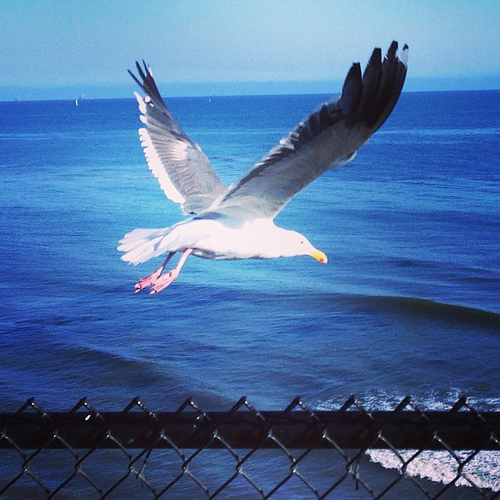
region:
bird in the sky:
[87, 35, 432, 333]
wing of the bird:
[241, 30, 438, 215]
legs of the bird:
[95, 250, 192, 335]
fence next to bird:
[190, 355, 330, 495]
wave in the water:
[391, 281, 441, 336]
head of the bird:
[270, 207, 340, 288]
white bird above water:
[85, 35, 435, 301]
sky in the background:
[222, 15, 294, 70]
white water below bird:
[423, 454, 455, 496]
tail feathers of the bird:
[118, 218, 188, 269]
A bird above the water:
[121, 64, 417, 289]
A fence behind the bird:
[1, 410, 499, 499]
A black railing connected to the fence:
[5, 410, 499, 445]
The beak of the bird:
[311, 244, 327, 267]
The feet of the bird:
[140, 260, 177, 292]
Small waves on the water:
[366, 288, 487, 319]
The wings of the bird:
[129, 58, 404, 219]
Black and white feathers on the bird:
[252, 110, 372, 193]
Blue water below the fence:
[111, 307, 420, 383]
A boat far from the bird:
[74, 99, 81, 106]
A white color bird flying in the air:
[51, 34, 452, 311]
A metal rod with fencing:
[10, 408, 487, 481]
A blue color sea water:
[25, 118, 98, 220]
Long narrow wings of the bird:
[121, 40, 416, 170]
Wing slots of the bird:
[331, 35, 454, 115]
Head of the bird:
[279, 221, 335, 278]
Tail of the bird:
[103, 217, 178, 259]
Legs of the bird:
[129, 247, 200, 309]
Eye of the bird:
[292, 233, 309, 248]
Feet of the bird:
[132, 274, 171, 305]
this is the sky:
[63, 3, 132, 61]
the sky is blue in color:
[124, 1, 178, 35]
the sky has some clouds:
[231, 8, 295, 46]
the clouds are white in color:
[229, 37, 299, 67]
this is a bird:
[100, 40, 412, 292]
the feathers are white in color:
[213, 200, 258, 253]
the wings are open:
[112, 50, 412, 210]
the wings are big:
[121, 40, 424, 222]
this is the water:
[23, 111, 73, 260]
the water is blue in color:
[364, 177, 440, 275]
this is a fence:
[54, 454, 336, 497]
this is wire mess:
[211, 451, 334, 496]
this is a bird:
[95, 128, 387, 312]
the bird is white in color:
[192, 232, 248, 259]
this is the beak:
[313, 237, 347, 276]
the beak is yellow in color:
[308, 245, 326, 260]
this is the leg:
[158, 259, 187, 286]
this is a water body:
[380, 164, 482, 286]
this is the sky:
[181, 20, 316, 84]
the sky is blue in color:
[423, 24, 473, 61]